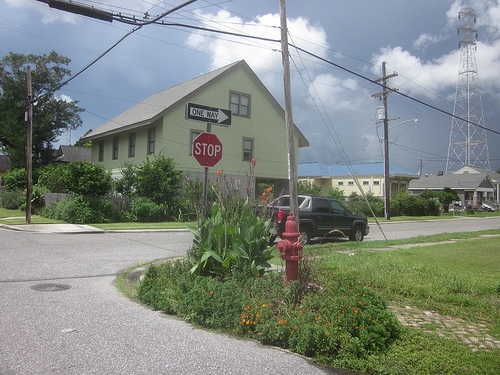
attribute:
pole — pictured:
[275, 1, 303, 215]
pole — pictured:
[370, 59, 400, 217]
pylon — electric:
[446, 5, 496, 185]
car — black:
[248, 192, 370, 245]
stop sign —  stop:
[184, 113, 281, 181]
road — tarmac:
[37, 285, 151, 357]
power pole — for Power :
[354, 37, 415, 235]